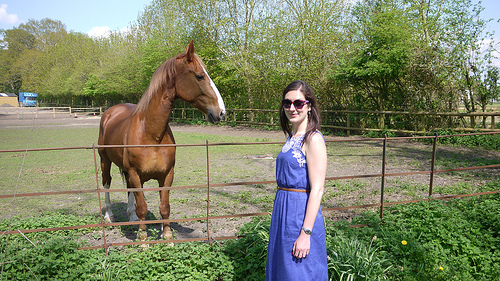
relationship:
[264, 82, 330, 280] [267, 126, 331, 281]
woman wearing dress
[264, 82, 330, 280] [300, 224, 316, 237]
woman wearing watch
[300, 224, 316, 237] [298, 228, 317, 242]
watch on wrist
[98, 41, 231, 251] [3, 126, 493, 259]
horse behind fence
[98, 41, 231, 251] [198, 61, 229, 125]
horse has white patch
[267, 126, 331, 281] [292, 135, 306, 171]
dress has white pattern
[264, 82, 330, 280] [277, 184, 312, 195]
woman wearing belt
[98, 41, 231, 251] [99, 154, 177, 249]
horse has legs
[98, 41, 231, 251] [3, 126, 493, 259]
horse standing near fence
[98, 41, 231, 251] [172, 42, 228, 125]
horse has brown head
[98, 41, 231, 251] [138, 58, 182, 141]
horse has neck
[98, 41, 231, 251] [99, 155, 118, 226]
horse has leg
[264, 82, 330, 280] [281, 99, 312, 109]
woman wearing sunglasses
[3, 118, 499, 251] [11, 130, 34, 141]
field has grass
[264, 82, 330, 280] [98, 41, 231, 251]
woman beside horse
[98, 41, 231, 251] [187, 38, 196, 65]
horse has ear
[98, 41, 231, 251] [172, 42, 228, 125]
horse has head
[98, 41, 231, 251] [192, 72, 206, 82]
horse has eye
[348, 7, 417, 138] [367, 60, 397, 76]
tree has leaves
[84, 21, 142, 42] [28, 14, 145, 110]
clouds over trees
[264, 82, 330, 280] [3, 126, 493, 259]
woman beside fence